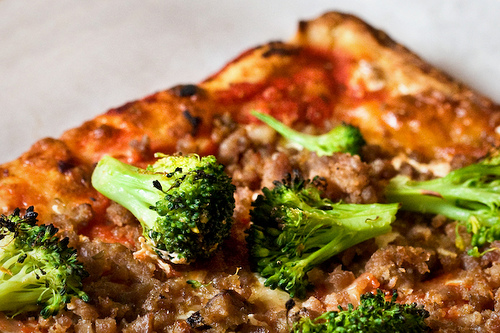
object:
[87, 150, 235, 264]
broccoli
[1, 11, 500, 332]
pizza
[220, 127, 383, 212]
meat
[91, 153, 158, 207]
stems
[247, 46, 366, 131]
sauce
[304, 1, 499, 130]
crust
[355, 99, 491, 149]
cheese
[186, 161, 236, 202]
florets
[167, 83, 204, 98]
spots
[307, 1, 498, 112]
edge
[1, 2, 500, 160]
plate